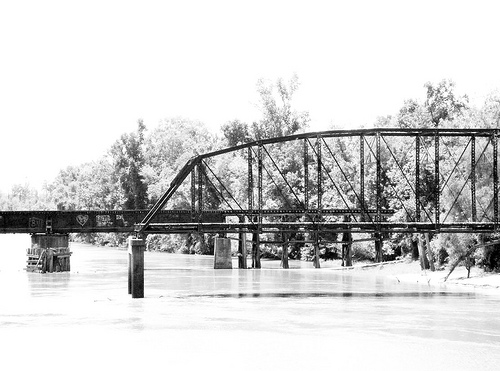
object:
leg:
[125, 218, 150, 298]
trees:
[98, 132, 151, 249]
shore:
[11, 215, 498, 287]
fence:
[192, 127, 495, 218]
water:
[8, 240, 495, 369]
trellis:
[142, 119, 498, 224]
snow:
[1, 69, 498, 369]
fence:
[236, 221, 431, 276]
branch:
[444, 252, 463, 280]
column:
[27, 232, 70, 272]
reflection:
[173, 287, 480, 298]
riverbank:
[73, 236, 125, 262]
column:
[213, 230, 232, 270]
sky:
[0, 0, 499, 209]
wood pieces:
[27, 243, 72, 273]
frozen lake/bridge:
[130, 160, 392, 363]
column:
[123, 237, 151, 297]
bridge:
[1, 128, 498, 294]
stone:
[213, 232, 235, 269]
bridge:
[160, 132, 497, 303]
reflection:
[24, 265, 74, 298]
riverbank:
[18, 251, 473, 312]